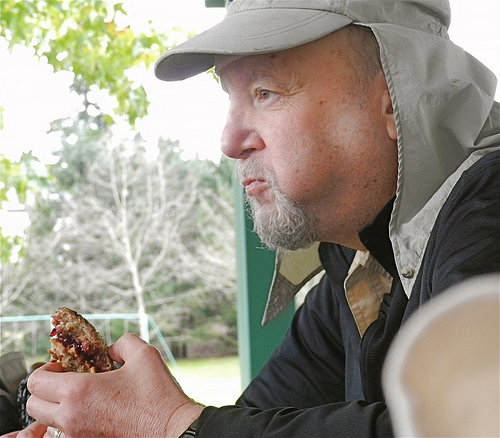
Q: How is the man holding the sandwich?
A: With his hand.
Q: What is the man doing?
A: He is eating.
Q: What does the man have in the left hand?
A: A sandwich.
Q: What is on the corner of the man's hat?
A: A button.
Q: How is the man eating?
A: With his mouth.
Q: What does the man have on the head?
A: A hat.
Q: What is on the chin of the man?
A: Facial hair.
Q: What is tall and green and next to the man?
A: A pillar.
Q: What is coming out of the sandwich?
A: Peanut butter and jelly.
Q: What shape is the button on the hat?
A: Circle.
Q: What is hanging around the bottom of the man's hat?
A: A neck protector.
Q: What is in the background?
A: Trees.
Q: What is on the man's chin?
A: Facial hair.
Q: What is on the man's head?
A: A hat with a neck flap.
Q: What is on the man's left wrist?
A: A watch.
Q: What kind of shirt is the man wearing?
A: Black and long sleeved.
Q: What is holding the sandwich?
A: The man's hand.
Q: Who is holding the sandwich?
A: The man.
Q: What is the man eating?
A: A sandwhich.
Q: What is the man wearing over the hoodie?
A: A hat.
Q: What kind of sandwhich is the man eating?
A: A peanut butter and jelly.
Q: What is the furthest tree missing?
A: Leaves.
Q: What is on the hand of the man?
A: A ring.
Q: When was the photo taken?
A: Day time.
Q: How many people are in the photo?
A: 1.